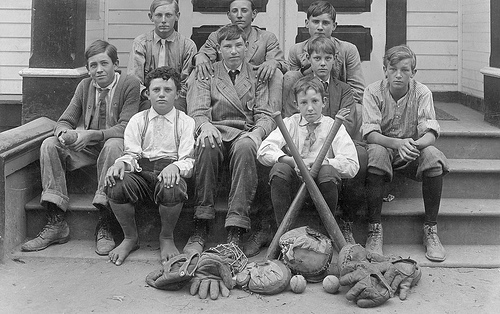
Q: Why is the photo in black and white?
A: It's vintage.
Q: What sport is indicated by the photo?
A: Baseball.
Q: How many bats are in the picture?
A: 2.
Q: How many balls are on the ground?
A: 2.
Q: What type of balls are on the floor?
A: Baseballs.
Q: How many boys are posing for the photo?
A: 9.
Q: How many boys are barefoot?
A: 1.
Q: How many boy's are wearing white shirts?
A: 2.